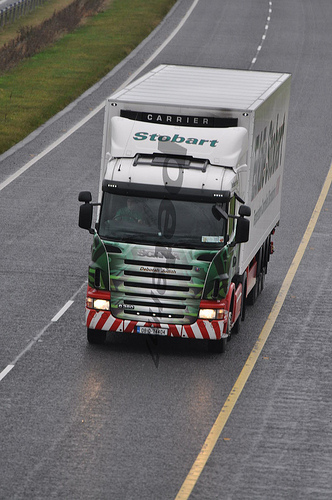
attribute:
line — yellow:
[170, 165, 330, 498]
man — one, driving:
[110, 194, 142, 220]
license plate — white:
[129, 319, 184, 349]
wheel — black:
[203, 291, 245, 350]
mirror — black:
[73, 187, 102, 238]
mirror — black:
[233, 199, 259, 247]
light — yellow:
[92, 294, 225, 324]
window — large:
[94, 193, 238, 250]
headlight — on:
[196, 306, 219, 321]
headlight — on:
[92, 298, 111, 310]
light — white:
[193, 304, 225, 324]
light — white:
[85, 290, 119, 317]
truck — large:
[68, 60, 299, 340]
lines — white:
[1, 1, 272, 384]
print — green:
[132, 127, 218, 148]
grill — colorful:
[100, 242, 217, 325]